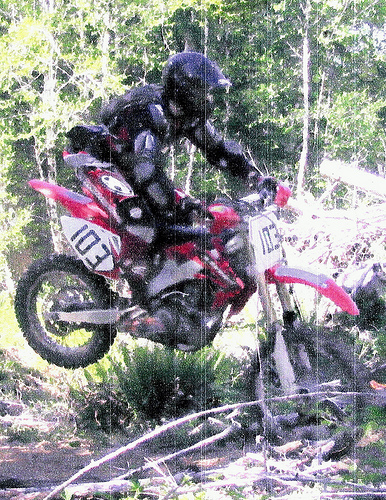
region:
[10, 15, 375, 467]
A motorcycle racer jumping over an obstacle during the race.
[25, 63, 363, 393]
a man riding a dirt bike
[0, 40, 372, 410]
a man on a dirt bike performing a stunt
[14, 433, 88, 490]
brown dirt of the ground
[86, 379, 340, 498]
several dead grey branches on the ground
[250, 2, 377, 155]
trees growing behind the dirt bike rider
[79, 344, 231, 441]
green leafy plant growing on the ground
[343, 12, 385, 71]
clear blue skies behind the trees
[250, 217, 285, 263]
black numbers on the white front of the dirt bike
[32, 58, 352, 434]
a man riding a red dirt bike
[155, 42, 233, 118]
the man's black motorcycle helmet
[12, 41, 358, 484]
biker on motorized bike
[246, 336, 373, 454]
front tire on bike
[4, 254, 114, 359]
rear tire on bike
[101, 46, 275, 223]
rider on the bike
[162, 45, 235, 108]
helmet on the bike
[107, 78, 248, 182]
top attire on biker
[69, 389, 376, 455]
branches from a tree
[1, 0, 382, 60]
leaves from the tree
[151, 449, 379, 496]
twigs on the ground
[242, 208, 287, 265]
number on front of bike